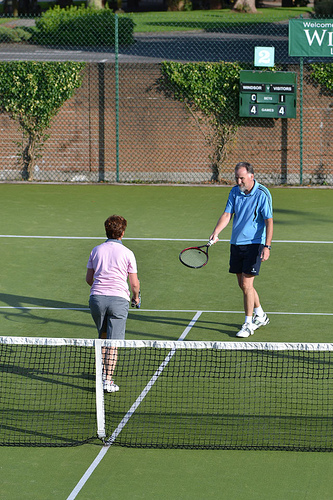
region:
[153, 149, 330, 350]
man wearing a blue shirt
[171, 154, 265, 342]
man wearing blue shorts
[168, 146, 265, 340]
man wearing tennis shoes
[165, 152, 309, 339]
man holding a tennis racket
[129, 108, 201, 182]
fence around a couch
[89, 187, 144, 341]
woman wearing a pink shirt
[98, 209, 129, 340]
woman wearing gray shorts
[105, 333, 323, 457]
tennis net on court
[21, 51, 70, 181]
trees near a court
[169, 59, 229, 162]
tree near a court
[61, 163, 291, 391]
a man and a woman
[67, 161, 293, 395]
two people on a tennis court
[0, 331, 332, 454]
black and white net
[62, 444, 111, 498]
white line painted on the court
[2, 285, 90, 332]
shadows on the court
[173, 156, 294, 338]
man sticking out his racket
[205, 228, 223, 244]
hand wrapped around the handle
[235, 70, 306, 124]
green, black, and white sign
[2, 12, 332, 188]
tall chain link fence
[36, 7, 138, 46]
small dark green bush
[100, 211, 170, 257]
The person has hair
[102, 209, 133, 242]
The person has brown hair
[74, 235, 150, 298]
The person is wearing a shirt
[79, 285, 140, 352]
The person is wearing shorts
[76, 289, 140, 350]
The person is wearing grey shorts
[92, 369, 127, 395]
The person is wearing shoees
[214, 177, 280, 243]
The man is wearing a shirt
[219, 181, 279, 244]
The man is wearing a blue shirt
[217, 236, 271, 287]
The man is wearing shorts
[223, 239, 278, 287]
The man is wearing dark blue shorts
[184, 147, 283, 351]
Man wearing blue shirt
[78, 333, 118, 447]
White line vertically aligned with net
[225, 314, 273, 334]
Wearing white tennis shoes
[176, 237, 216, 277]
Holding red and black racket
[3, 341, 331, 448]
Tennis net is short and black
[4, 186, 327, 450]
Floor is dark green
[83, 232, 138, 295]
Shirt of woman is pink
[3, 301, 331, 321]
Horizontal line behind man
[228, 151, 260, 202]
Man's head is gray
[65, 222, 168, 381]
Woman facing towards man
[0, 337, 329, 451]
a tennis court net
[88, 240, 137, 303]
woman wearing a pink shirt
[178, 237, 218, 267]
man holding a tennis racket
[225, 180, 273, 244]
a blue shirt with black stripe line on the shoulders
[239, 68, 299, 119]
a green scoreboard on a metal fence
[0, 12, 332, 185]
a green metal fence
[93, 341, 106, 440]
a white pole holding a tennis court net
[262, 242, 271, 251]
man wearing a black watch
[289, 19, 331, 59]
a green banner on a metal fence